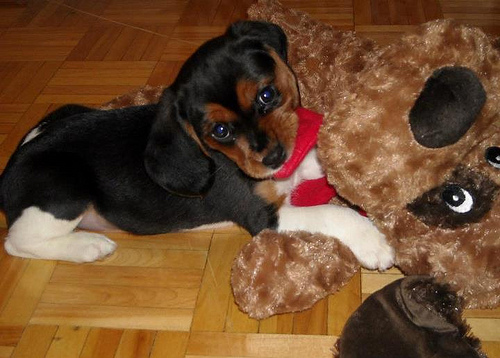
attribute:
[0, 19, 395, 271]
puppy — looking forward, black, brown, playing, white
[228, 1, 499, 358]
stuffed dog — brown, big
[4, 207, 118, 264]
foot — white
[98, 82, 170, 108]
foot — brown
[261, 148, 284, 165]
nose — black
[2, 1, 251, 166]
floor — wooden, brown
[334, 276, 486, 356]
ear — dark brown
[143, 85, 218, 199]
ear — black, floppy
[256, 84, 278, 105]
eye — round, black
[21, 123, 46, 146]
spot — white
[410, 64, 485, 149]
nose — fabric, brown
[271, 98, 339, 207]
bow — red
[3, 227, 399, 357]
floor — brown, hardwood, wood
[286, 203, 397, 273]
paw — white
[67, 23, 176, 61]
square — wood